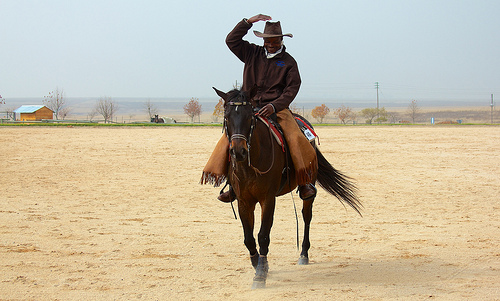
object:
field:
[0, 127, 500, 301]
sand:
[415, 146, 461, 198]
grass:
[84, 122, 136, 127]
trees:
[181, 96, 205, 126]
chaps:
[274, 109, 322, 187]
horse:
[210, 82, 361, 289]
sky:
[0, 0, 500, 118]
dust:
[403, 65, 453, 99]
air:
[46, 55, 96, 86]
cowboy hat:
[252, 19, 295, 39]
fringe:
[306, 166, 316, 182]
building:
[10, 100, 62, 124]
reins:
[226, 100, 250, 111]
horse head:
[210, 82, 262, 166]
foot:
[296, 182, 318, 200]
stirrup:
[218, 180, 237, 204]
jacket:
[224, 18, 301, 113]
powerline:
[302, 82, 376, 87]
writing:
[274, 59, 288, 68]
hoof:
[252, 276, 270, 291]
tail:
[316, 151, 364, 220]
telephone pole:
[487, 89, 495, 125]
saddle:
[258, 116, 287, 152]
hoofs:
[296, 250, 314, 267]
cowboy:
[196, 12, 322, 208]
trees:
[307, 101, 334, 125]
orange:
[314, 108, 326, 115]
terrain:
[108, 233, 173, 269]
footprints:
[119, 217, 147, 226]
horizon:
[0, 91, 500, 107]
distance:
[76, 98, 150, 117]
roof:
[14, 104, 49, 114]